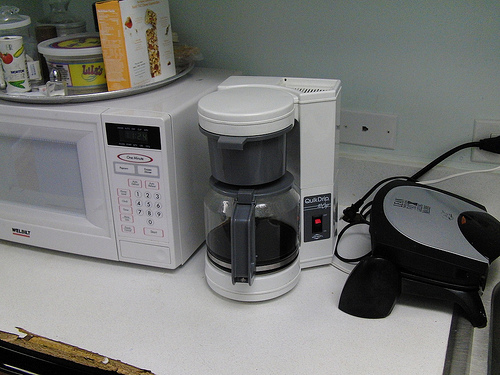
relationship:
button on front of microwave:
[119, 238, 172, 264] [1, 66, 242, 270]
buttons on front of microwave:
[112, 149, 165, 238] [1, 66, 242, 270]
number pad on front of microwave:
[133, 187, 163, 226] [1, 66, 242, 270]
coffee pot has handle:
[202, 169, 302, 285] [227, 200, 257, 286]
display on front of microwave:
[106, 122, 163, 149] [1, 66, 242, 270]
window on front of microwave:
[1, 136, 88, 217] [1, 66, 242, 270]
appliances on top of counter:
[2, 65, 499, 327] [0, 182, 455, 374]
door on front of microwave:
[0, 102, 120, 263] [1, 66, 242, 270]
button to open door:
[119, 238, 172, 264] [0, 102, 120, 263]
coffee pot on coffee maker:
[202, 169, 302, 285] [196, 74, 342, 302]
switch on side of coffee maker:
[311, 213, 324, 236] [196, 74, 342, 302]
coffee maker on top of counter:
[196, 74, 342, 302] [0, 182, 455, 374]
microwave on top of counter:
[1, 66, 242, 270] [0, 182, 455, 374]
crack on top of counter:
[2, 324, 153, 374] [0, 182, 455, 374]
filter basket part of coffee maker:
[197, 123, 294, 185] [196, 74, 342, 302]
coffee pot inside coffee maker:
[202, 169, 302, 285] [196, 74, 342, 302]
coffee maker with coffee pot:
[196, 74, 342, 302] [202, 169, 302, 285]